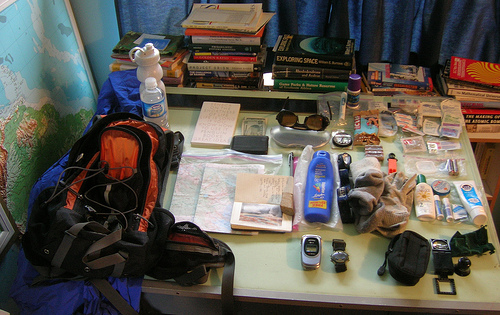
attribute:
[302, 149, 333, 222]
bottle — blue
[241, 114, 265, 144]
cash — stacked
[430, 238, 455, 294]
compass — travel sized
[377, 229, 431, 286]
camera case — nylon, black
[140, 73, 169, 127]
water bottle — plastic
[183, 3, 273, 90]
books — stacked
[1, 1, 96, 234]
map — large, turned sideways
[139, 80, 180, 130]
water — bottled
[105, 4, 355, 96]
books — in pile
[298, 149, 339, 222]
bottle — blue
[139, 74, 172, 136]
bottle — water bottle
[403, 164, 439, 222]
bottle — plastic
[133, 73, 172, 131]
bottle — plastic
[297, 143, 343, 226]
bottle — plastic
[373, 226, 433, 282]
bag — small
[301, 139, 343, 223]
bottle — Blue, large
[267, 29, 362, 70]
book — exploring space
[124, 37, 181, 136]
bottle — large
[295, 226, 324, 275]
flip phone — silver